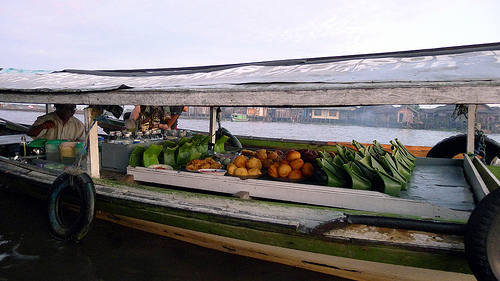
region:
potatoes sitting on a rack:
[227, 149, 260, 176]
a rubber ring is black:
[43, 165, 96, 244]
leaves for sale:
[314, 135, 417, 194]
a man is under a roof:
[27, 103, 86, 142]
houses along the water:
[220, 105, 499, 130]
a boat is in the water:
[229, 112, 251, 123]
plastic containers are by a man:
[35, 138, 86, 164]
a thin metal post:
[207, 106, 217, 145]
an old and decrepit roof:
[0, 44, 499, 104]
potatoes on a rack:
[265, 149, 315, 179]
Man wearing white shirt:
[29, 102, 84, 139]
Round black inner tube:
[47, 170, 94, 242]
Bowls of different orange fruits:
[192, 144, 309, 178]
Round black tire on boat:
[463, 183, 499, 278]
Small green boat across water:
[228, 111, 248, 121]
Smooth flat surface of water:
[222, 120, 434, 147]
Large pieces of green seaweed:
[135, 135, 226, 165]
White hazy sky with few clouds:
[2, 2, 494, 53]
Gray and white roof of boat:
[6, 49, 499, 101]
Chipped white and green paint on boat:
[101, 178, 329, 259]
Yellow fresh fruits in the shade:
[271, 153, 306, 179]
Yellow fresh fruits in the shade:
[225, 147, 250, 177]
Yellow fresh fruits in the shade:
[255, 140, 271, 155]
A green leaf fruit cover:
[372, 166, 397, 191]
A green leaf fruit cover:
[336, 160, 368, 192]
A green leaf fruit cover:
[315, 160, 336, 184]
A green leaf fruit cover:
[138, 145, 165, 167]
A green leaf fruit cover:
[162, 139, 177, 169]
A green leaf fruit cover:
[179, 139, 208, 158]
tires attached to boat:
[43, 127, 499, 279]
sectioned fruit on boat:
[125, 121, 414, 198]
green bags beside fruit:
[318, 133, 413, 193]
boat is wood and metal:
[1, 43, 498, 279]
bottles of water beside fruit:
[101, 126, 188, 168]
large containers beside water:
[41, 135, 82, 166]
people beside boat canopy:
[28, 102, 183, 145]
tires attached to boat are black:
[47, 131, 499, 278]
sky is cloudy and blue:
[0, 3, 499, 110]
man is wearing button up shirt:
[23, 112, 87, 149]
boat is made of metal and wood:
[0, 39, 498, 279]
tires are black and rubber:
[47, 123, 499, 279]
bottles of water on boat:
[105, 128, 184, 173]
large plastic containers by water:
[42, 140, 87, 172]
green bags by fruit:
[318, 138, 414, 200]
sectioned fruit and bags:
[129, 133, 414, 194]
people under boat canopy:
[27, 102, 187, 146]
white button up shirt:
[31, 113, 85, 153]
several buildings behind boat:
[1, 100, 498, 134]